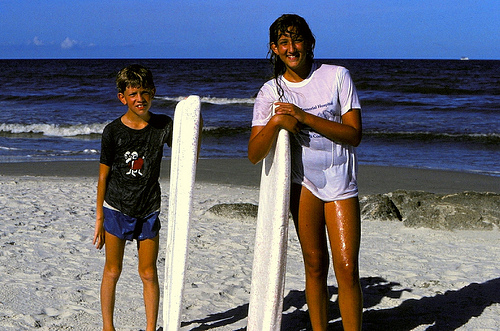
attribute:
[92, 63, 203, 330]
person — standing, boy, tan, young, wet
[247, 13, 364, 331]
person — standing, woman, wet, tan, young, smiling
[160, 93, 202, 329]
surfboard — foam, white, styrofoam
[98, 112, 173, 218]
shirt — black, wet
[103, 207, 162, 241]
shorts — blue, wet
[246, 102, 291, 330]
surfboard — foam, white, styrofoam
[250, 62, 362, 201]
shirt — white, wet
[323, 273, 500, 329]
shadow — dark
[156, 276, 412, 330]
shadow — dark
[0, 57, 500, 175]
water — blue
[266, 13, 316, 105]
hair — wet, brown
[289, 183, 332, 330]
leg — wet, tan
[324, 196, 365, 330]
leg — wet, tan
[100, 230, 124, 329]
leg — wet, tan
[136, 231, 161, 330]
leg — wet, tan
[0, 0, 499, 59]
sky — clear